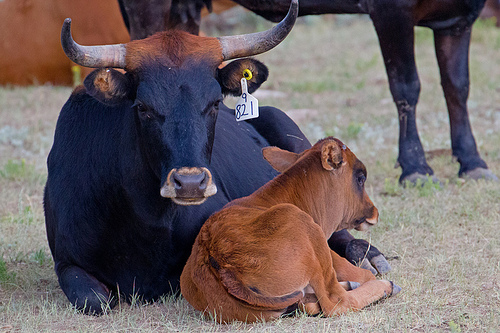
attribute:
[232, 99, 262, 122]
numbers — white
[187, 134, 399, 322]
calf — brown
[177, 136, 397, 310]
cow — brown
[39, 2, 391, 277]
cow — adult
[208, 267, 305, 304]
tail — curled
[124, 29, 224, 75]
top — brown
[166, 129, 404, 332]
calf — small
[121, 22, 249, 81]
fur — brown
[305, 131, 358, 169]
ear — brown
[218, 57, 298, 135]
tag — yellow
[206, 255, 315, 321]
tail — curled